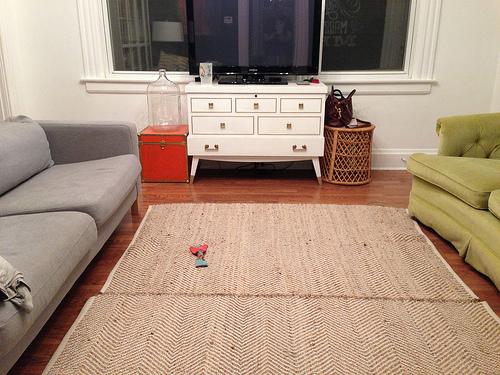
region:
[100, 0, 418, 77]
a large window at the back of the room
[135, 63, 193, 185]
a red chest with a jug on top of it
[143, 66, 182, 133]
a large jug on top of a chest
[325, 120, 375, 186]
a round wicker side table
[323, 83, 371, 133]
a purse on top of the wicker table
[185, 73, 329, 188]
a white chest of drawers near the window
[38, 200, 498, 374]
a set of woven rugs on the floor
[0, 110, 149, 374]
a gray colored couch in the living room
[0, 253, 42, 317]
a piece of clothing on the couch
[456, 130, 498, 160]
buttons on the green couch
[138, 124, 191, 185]
Red trunk with gold trim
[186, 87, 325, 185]
White stand with gold trim and drawer pulls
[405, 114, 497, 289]
Green sofa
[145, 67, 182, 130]
Large clear glass jug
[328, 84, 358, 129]
Brown purse sitting on wicker stool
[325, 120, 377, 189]
Brown wicker stool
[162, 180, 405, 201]
Hard wood flooring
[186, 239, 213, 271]
Red and blue ribbon laying on floor rug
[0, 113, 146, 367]
Grey two cushion couch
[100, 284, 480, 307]
Seam on floor rugs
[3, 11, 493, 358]
Picture of a living room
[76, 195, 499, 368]
A square area rug.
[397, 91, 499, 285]
Green couch on right side.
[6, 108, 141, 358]
Grey couch on left side.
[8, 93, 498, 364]
Two couches facing each other.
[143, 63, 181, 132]
A large glass jar.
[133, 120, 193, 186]
A sqaure organe storage box.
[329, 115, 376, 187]
A roung bamboo container.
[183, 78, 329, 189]
White chest of drawers.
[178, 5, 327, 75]
Flat screen tv.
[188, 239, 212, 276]
a toy on the floor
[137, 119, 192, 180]
a chest on the floor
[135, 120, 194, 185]
the chest is red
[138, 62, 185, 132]
a glass bottle on the chest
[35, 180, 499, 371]
a rug on the floor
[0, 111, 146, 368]
a sofa is left of the rug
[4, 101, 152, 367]
this sofa is grey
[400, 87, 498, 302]
the sofa is right of the rug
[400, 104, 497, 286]
the sofa is lime green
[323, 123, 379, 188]
a straw stool on the ground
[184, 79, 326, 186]
White living room dresser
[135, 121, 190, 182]
Orange cube shaped chest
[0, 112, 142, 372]
gray couch with wood legs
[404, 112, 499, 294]
Green love seat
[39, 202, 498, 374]
Tan burlap living room rugs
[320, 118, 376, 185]
Round wicker basket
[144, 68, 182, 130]
Large empty glass bottle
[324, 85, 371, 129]
Large brown leather purse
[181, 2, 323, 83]
Large flat screen television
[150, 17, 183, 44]
Reflection of a white lamp shade